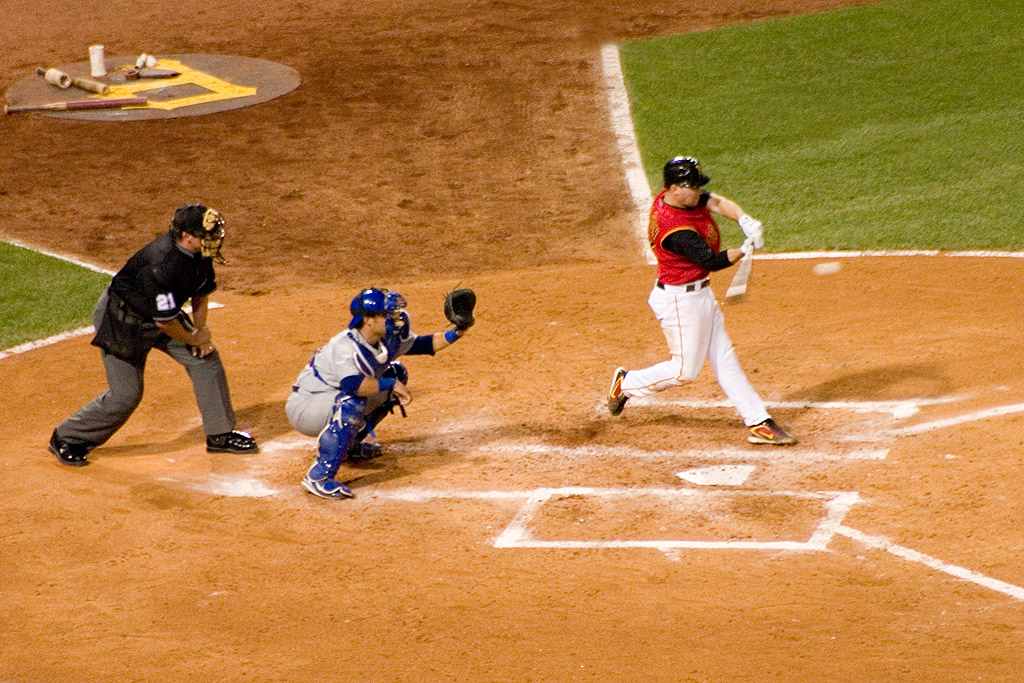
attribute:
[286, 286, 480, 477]
outfit — blue, white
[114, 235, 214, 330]
shirt — black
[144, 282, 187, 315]
numbers — white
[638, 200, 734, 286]
shirt — red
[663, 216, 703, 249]
trim — yellow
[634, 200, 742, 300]
shirt — yellow, red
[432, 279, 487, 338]
catcher's mitt — brown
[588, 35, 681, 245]
lines — white